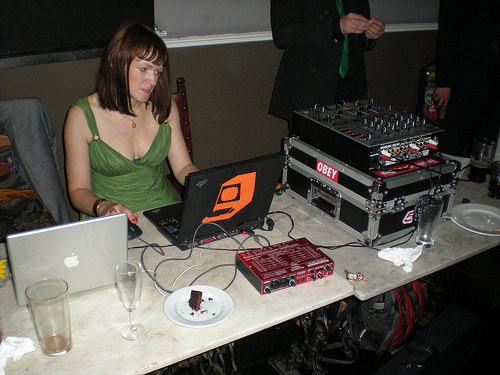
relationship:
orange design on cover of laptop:
[207, 173, 276, 232] [145, 149, 288, 253]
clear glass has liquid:
[20, 273, 81, 363] [43, 329, 72, 353]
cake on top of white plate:
[187, 285, 214, 315] [157, 285, 240, 330]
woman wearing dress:
[60, 24, 203, 232] [76, 98, 180, 220]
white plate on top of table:
[163, 273, 239, 328] [167, 278, 237, 328]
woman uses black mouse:
[60, 24, 203, 232] [108, 207, 148, 247]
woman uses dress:
[50, 24, 215, 231] [76, 98, 180, 220]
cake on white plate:
[188, 290, 203, 312] [163, 284, 235, 328]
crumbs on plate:
[473, 208, 494, 231] [442, 188, 498, 240]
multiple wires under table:
[139, 222, 379, 299] [101, 184, 493, 314]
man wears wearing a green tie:
[257, 1, 398, 144] [332, 1, 370, 79]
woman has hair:
[60, 24, 203, 232] [88, 23, 178, 123]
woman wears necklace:
[50, 24, 215, 231] [113, 99, 154, 128]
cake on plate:
[188, 290, 203, 312] [157, 279, 237, 329]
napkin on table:
[370, 237, 428, 275] [252, 166, 497, 306]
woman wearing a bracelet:
[60, 24, 203, 232] [81, 193, 111, 216]